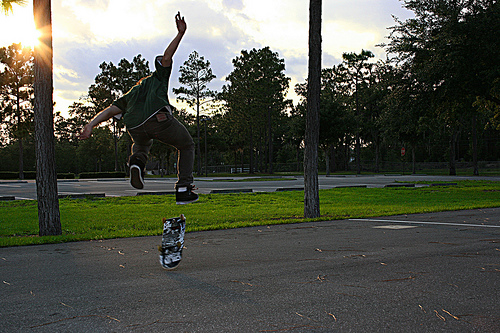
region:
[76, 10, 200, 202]
man jumping on a skateboard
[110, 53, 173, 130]
green shirt on man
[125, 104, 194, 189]
black pants on man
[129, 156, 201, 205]
black shoes on man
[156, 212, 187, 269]
upside-down skateboard under man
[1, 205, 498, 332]
parking lot under man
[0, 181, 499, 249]
grassy median in parking lot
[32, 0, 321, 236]
trees behind man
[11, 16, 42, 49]
sun shining through clouds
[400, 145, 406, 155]
a stop sign behind the parking lot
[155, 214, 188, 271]
An upside down skateboard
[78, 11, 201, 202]
A man soaring in the air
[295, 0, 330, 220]
A tall thin tree trunk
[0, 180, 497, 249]
A long patch of grass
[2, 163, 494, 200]
A large parking lot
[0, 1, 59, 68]
A bright setting sun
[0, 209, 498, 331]
A long patch of asphalt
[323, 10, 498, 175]
A lush green forest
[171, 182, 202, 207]
a pair of black sneakers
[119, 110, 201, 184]
a pair of brown jeans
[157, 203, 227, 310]
skateboard located in midair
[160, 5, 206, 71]
skaters extended right hand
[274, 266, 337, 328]
grey asphalt on ground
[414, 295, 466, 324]
brown sticks on asphalt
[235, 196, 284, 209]
green patch of grass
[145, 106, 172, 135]
brown tag on boy's pants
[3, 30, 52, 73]
bright sun shining throught the trees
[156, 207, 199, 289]
black and white skateboard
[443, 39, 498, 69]
green tree fill with leaves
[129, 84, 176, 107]
green shirt on the back of the skateboarder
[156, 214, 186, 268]
black and white skateboard in the air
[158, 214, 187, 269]
skate board with skull designs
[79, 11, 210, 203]
man jumping in the air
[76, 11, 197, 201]
man doing a kick flip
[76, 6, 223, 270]
skateboarder performing a trick in the air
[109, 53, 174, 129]
green shirt on the man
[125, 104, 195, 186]
black jeans on the man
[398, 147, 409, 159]
red stop sign in the distance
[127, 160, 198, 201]
black shoes on the man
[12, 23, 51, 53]
sun coming out from behind the clouds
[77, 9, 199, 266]
a skateboarder performing trick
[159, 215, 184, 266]
black and white bottom of skateboard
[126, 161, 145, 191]
a black and white shoe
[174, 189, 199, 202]
a black and white shoe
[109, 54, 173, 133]
a green t-shirt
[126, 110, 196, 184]
a pair of men's jeans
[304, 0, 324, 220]
a tall tree trunk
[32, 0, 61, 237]
a tall tree trunk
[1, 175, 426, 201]
a paved parking lot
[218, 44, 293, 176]
large green tree in distance